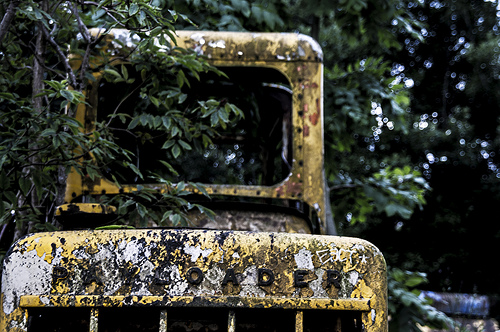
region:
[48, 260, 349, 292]
black writing on the vehicle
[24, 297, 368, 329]
a grill on the vehicle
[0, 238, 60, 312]
peeled paint on the vehicle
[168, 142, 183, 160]
a green leaf on the tree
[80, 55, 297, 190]
the window of a vehicle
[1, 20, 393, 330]
a yellow vehicle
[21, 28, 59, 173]
a brown tree branch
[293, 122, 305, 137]
a bolt on the vehicle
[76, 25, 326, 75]
the roof of a vehicle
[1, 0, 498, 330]
a leafy green tree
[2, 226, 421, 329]
the back of a tractor.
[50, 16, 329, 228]
the cab of a tractor.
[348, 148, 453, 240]
a bush filled with leaves.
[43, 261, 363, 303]
a company name on a logo.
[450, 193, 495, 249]
a patch of black forest.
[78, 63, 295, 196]
a window on a tractor.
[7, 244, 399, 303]
faded paint on a tractor.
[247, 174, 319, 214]
rust on a tractor.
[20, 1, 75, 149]
tree branches in a jungle.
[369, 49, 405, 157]
shiny leaves in a jungle.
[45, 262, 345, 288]
payloader in black letters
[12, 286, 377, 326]
the grill of a payloader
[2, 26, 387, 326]
an abandoned yellow payloader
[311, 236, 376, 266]
graffiti on the front of a payloader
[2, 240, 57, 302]
white area where paint has chipped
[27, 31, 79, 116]
a tree branch hanging over the front of a payloader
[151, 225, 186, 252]
black marks on the front of a payloader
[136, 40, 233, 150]
green leaves in the window opening of a payloader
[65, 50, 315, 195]
a glassless window opening on a payloader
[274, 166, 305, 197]
a rusted area near the window opening of a payloader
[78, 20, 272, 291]
the leaves are green and visible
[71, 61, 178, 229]
the leaves are green and visible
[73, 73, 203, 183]
the leaves are green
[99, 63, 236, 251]
the leaves are green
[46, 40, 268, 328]
the leaves are green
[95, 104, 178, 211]
the leaves are green